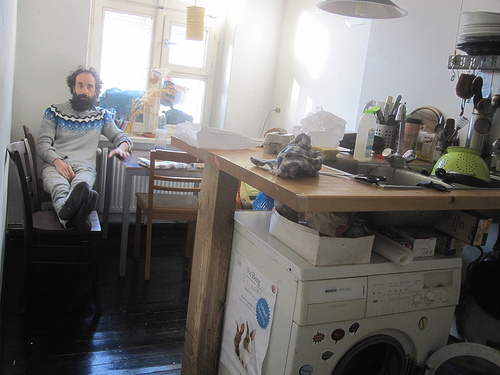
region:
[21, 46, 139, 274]
man sitting at a dining table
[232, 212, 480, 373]
a white laundry machine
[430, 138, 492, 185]
a yellow colander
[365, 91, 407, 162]
cooking utensils on the counter top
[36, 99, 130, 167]
the man is wearing a grey sweater with a blue and white design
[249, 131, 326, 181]
rag sitting on counter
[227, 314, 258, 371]
picture of rabbits on a paper hanging on the laundry maching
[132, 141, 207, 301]
unused wooden chair next to the man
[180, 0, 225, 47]
hanging light over the dining table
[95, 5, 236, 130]
window behind the man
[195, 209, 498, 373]
A white washing machine.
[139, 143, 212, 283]
A light brown wooden chair.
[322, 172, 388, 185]
A pair of scissors with black handles.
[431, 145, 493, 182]
A green strainer.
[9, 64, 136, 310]
A man sitting down with his legs extended on a chair.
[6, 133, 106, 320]
A dark brown wooden chair.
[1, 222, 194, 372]
Black colored hardwood floors.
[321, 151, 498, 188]
A silver kitchen sink.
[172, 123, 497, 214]
A Wooden countertop.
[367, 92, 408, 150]
Kitchen utensils.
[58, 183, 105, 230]
man wearing socks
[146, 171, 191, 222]
a chair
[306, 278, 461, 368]
a white washer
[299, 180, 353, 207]
the counter is wooden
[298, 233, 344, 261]
a white box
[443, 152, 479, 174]
a green bowl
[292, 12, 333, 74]
a reflection of light on the wall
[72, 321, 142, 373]
a reflection of light on the floor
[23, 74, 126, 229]
the man is sitting down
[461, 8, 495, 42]
white dishes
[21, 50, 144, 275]
Man sitting with legs up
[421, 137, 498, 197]
green colander on table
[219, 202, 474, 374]
white washing machine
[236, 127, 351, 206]
blue and white wash rag on table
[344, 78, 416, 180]
utensils in container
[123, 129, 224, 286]
brown wooden chair at table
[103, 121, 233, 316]
little square table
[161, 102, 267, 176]
white plastic bag on table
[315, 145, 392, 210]
scissors on the table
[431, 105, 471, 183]
utensils in container on table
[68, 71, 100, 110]
man's bearded face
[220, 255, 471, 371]
white portable washing machine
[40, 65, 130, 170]
man wearing gray sweater, blue and white design on it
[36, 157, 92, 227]
man's feet cross resting on dinning chair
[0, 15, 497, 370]
small apartment with dinng and kitchen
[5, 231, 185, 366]
dark wood flooring in the apartment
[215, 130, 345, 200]
counter top with a white and blue cloth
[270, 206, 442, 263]
white boxes on the washing machine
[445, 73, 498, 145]
cooking utensils hang on the far wall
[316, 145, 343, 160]
a yewllow sponge on the sink